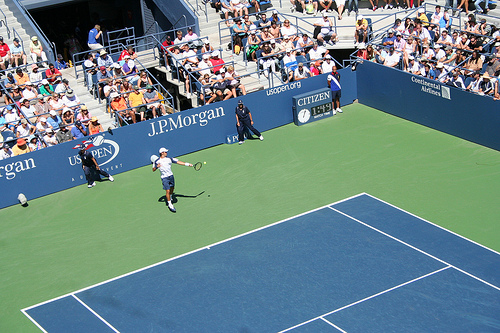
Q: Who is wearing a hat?
A: The man is wearing a hat.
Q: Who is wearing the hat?
A: The man is wearing a hat.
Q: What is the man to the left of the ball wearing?
A: The man is wearing a hat.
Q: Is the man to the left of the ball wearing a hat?
A: Yes, the man is wearing a hat.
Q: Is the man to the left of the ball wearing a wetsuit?
A: No, the man is wearing a hat.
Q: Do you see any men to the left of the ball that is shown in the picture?
A: Yes, there is a man to the left of the ball.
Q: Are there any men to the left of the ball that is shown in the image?
A: Yes, there is a man to the left of the ball.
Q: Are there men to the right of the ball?
A: No, the man is to the left of the ball.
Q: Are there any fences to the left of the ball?
A: No, there is a man to the left of the ball.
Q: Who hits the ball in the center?
A: The man hits the ball.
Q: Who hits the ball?
A: The man hits the ball.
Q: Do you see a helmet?
A: No, there are no helmets.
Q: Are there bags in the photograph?
A: No, there are no bags.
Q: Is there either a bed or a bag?
A: No, there are no bags or beds.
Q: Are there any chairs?
A: Yes, there is a chair.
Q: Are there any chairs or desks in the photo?
A: Yes, there is a chair.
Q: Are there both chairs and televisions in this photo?
A: No, there is a chair but no televisions.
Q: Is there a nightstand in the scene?
A: No, there are no nightstands.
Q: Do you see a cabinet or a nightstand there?
A: No, there are no nightstands or cabinets.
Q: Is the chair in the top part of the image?
A: Yes, the chair is in the top of the image.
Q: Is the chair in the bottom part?
A: No, the chair is in the top of the image.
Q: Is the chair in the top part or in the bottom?
A: The chair is in the top of the image.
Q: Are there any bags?
A: No, there are no bags.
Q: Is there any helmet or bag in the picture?
A: No, there are no bags or helmets.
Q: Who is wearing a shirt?
A: The man is wearing a shirt.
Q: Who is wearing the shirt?
A: The man is wearing a shirt.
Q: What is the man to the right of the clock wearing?
A: The man is wearing a shirt.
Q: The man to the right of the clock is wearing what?
A: The man is wearing a shirt.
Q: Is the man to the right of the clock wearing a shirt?
A: Yes, the man is wearing a shirt.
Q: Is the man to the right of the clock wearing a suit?
A: No, the man is wearing a shirt.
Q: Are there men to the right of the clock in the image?
A: Yes, there is a man to the right of the clock.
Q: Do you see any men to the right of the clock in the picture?
A: Yes, there is a man to the right of the clock.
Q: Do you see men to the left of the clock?
A: No, the man is to the right of the clock.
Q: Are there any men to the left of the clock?
A: No, the man is to the right of the clock.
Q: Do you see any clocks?
A: Yes, there is a clock.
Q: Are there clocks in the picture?
A: Yes, there is a clock.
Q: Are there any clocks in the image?
A: Yes, there is a clock.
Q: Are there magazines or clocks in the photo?
A: Yes, there is a clock.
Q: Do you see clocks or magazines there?
A: Yes, there is a clock.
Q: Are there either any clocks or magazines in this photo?
A: Yes, there is a clock.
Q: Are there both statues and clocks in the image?
A: No, there is a clock but no statues.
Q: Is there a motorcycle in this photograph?
A: No, there are no motorcycles.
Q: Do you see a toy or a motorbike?
A: No, there are no motorcycles or toys.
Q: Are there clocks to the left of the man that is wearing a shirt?
A: Yes, there is a clock to the left of the man.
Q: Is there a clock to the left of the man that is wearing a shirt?
A: Yes, there is a clock to the left of the man.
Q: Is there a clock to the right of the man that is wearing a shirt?
A: No, the clock is to the left of the man.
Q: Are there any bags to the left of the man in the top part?
A: No, there is a clock to the left of the man.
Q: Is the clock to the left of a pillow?
A: No, the clock is to the left of a man.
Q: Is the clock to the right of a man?
A: No, the clock is to the left of a man.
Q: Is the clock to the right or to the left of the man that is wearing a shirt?
A: The clock is to the left of the man.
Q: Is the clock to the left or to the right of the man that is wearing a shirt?
A: The clock is to the left of the man.